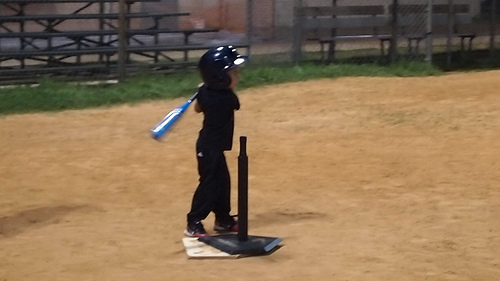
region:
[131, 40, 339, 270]
little boy playing t ball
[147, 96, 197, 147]
blue tee ball bat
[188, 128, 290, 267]
black tee ball stand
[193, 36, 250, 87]
batting helmet for a child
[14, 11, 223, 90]
bleachers at the baseball fiels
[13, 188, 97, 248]
shadow on the ground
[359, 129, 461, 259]
foot prints in the dirt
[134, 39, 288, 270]
child playing tee ball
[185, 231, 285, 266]
home plate at a baseball field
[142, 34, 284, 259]
little boy swinging a bat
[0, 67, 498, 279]
brown dirt on the ground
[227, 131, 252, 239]
a black batting tee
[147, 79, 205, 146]
a blue and black baseball bat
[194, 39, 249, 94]
a black helmet on the boy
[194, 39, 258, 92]
a head on the boy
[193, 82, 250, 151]
a black tee shirt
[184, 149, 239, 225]
a pair of black pants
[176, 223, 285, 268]
a white base of a tee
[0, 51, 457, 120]
a patch of green grass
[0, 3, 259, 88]
bleachers behind the grass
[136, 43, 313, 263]
litte kid playing t-ball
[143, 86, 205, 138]
small blue bat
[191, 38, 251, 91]
tiny, shiny black helmet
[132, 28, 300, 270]
little kid at bat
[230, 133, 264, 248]
t-ball stand with no ball on it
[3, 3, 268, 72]
empty stands along the outskirts of the field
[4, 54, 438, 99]
thin strip of green grass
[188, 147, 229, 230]
black baseball pants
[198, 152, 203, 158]
white triangle on the behind of the pants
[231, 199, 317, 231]
shadow on the dirt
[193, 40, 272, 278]
little kid holding bat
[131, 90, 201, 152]
blue baseball bat held by boy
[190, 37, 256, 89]
black helmet worn by boy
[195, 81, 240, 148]
black shirt worn by boy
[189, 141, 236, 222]
black pants worn by boy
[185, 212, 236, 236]
black and red shoes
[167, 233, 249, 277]
home plate for baseball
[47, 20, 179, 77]
stands for fans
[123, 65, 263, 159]
boy swinging baseball bat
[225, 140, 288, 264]
tee for tee ball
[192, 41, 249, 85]
the helmet is blue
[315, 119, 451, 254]
the ground is brown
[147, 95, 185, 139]
the abt is blue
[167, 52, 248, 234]
the boys is small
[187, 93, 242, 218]
the attire is black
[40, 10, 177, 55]
the benches are made of wood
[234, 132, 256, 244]
the pole is black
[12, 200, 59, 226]
the shadow is on the ground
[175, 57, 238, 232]
the boy is about to hit the ball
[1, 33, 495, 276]
the game is baseball